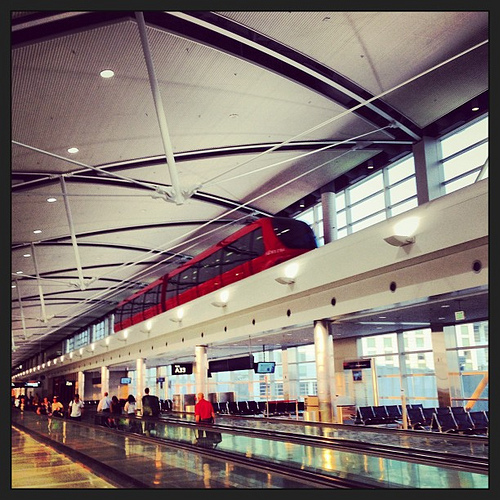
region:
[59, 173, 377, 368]
red train on track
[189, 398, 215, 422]
person wearing red shirt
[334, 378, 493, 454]
blue chairs lined in a row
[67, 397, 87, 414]
person wearing white shirt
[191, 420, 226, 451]
man holding black bags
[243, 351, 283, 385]
television monitor turned on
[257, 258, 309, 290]
light fixture facing upward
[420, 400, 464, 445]
chairs have silver trim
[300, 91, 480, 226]
window has black trim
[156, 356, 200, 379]
black sign with white writing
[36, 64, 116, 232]
row of circular overhead lighting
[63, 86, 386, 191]
beams in the ceiling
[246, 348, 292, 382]
overhead monitors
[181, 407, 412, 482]
large conveyor belt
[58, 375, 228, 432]
people walking on conveyor belt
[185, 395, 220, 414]
man wearing red shirt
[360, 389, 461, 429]
row of blue seating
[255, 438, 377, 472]
shine on the floor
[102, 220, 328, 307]
red train on overhead track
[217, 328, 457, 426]
large windows in building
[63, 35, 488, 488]
the scene is in a subway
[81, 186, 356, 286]
the carriage is red in colour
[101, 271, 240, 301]
it has windows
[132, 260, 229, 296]
the windows are closed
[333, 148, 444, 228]
the windows are closed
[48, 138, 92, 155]
the lights are on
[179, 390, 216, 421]
the shirt is red in colour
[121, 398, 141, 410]
the shirt is white in colour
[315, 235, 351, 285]
the wall is white in colour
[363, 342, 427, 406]
the windows are shut